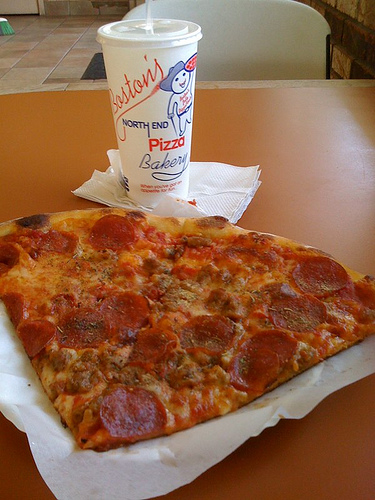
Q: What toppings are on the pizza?
A: Pepperoni.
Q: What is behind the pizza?
A: A cup.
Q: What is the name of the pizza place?
A: Boston's North End Pizza.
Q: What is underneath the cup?
A: A napkin.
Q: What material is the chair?
A: Plastic.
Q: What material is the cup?
A: Paper.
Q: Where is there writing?
A: On the cup.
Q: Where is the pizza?
A: On a table.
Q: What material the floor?
A: Tiles.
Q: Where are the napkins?
A: Under the cup.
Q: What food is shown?
A: Pizza.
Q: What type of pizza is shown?
A: Meat.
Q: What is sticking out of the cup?
A: Straw.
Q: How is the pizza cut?
A: In two slices.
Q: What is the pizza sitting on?
A: Paper.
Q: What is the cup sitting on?
A: Paper napkin.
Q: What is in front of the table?
A: A chair.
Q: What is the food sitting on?
A: A table.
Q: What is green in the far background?
A: Broom bristles.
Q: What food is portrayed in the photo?
A: Pizza.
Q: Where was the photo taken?
A: Pizzeria.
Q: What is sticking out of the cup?
A: Straw.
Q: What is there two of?
A: Pizza slices.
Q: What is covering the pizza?
A: Pepperoni.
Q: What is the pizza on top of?
A: Paper.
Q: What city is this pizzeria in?
A: Boston.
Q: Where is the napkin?
A: Under cup.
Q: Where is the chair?
A: By table.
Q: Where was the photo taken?
A: Restaurant.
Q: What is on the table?
A: Pizza, napkins and a drink.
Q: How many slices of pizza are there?
A: Two.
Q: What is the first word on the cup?
A: Boston's.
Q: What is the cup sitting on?
A: A napkin.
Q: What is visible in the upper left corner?
A: A broom.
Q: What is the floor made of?
A: Tile.